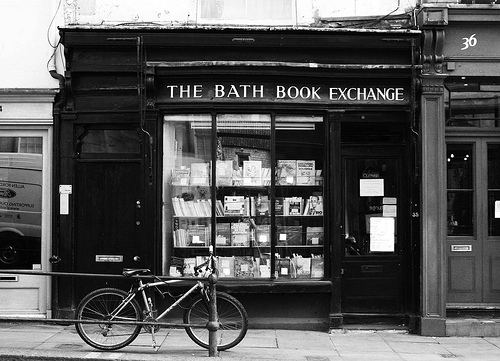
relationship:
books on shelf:
[171, 161, 324, 279] [169, 182, 324, 278]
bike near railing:
[74, 243, 248, 349] [0, 268, 218, 358]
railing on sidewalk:
[0, 268, 218, 358] [0, 320, 498, 361]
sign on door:
[369, 216, 394, 252] [341, 143, 406, 312]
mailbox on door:
[95, 254, 123, 262] [77, 161, 145, 314]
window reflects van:
[0, 136, 41, 269] [0, 152, 41, 269]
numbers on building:
[460, 33, 477, 52] [420, 3, 500, 335]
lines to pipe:
[46, 1, 63, 70] [48, 70, 64, 319]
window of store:
[163, 115, 325, 282] [49, 26, 422, 330]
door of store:
[341, 143, 406, 312] [49, 26, 422, 330]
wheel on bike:
[183, 290, 247, 351] [74, 243, 248, 349]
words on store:
[166, 83, 403, 102] [49, 26, 422, 330]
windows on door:
[345, 158, 397, 255] [341, 143, 406, 312]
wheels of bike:
[74, 287, 248, 351] [74, 243, 248, 349]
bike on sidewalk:
[74, 243, 248, 349] [0, 320, 498, 361]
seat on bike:
[123, 267, 150, 277] [74, 243, 248, 349]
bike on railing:
[74, 243, 248, 349] [0, 268, 218, 358]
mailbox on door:
[95, 254, 123, 262] [341, 143, 406, 312]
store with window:
[49, 26, 422, 330] [163, 115, 325, 282]